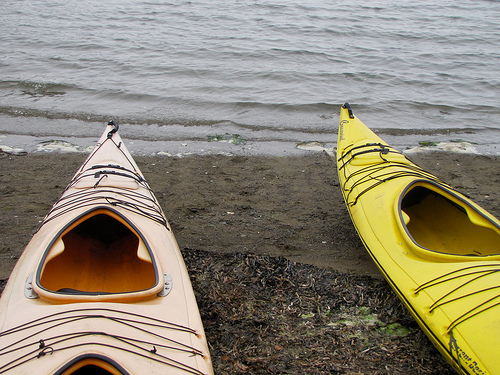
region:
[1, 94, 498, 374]
two kayaks at mouth of the sea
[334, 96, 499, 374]
1 kayak is yellow 1 kayak is peach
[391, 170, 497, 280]
interior cockpit of yellow kayak is yellow, in shadow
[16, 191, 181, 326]
interior cockpit of peach kayak is a woody orange colour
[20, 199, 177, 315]
coaming around cockpit of peach kayak held on with silvertone brackets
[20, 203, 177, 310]
silvertone brackets held on w/ silvertone bolts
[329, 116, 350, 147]
yellow kayak has name @ tip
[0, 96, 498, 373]
plenty of straps across both kayaks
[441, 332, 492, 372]
yellow kayak has brand name @ lower right corner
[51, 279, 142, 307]
seat is very slightly visible in peach kayak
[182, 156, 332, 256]
dark brown wet sand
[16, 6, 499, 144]
the water is calm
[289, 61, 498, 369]
yellow kayak on the beach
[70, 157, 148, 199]
hatch with tie-down straps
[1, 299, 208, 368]
shock cord deck rigging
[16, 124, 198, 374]
kayak for two people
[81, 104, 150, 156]
grab handle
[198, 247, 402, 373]
seaweed and other debris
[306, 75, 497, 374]
the kayak resembles a banana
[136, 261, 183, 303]
metal plate with screws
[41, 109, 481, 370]
2 kayaks on beach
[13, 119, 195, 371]
orange colored kayak on shore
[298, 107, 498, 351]
yellow kayak on shore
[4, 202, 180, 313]
small opening on kayak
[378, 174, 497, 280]
small opening on kayak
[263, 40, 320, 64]
waves in the ocean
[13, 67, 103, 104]
waves in the ocean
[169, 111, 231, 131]
waves in the ocean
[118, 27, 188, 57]
waves in the ocean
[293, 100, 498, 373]
the canoe by the water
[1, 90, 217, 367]
the canoe by the water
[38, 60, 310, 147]
the wave on the water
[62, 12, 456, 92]
the water is calm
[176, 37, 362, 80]
the water is opaque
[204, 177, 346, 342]
the dirt beside the water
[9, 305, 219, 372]
the rope on the canoe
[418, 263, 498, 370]
the rope on the canoe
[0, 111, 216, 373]
the canoe is beige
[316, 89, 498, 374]
the canoe is yellow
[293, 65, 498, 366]
bright yellow canoe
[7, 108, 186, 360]
light beige colored canoe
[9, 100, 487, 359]
dark wet sandy beach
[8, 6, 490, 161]
muddy grey rippled water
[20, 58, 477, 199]
small waves washing up shore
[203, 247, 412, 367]
dead leaves and weeds in the sand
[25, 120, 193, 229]
black ties on a canoe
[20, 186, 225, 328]
traingle shaped canoe opening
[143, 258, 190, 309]
small silver bolted plate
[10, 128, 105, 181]
white foam on top of water